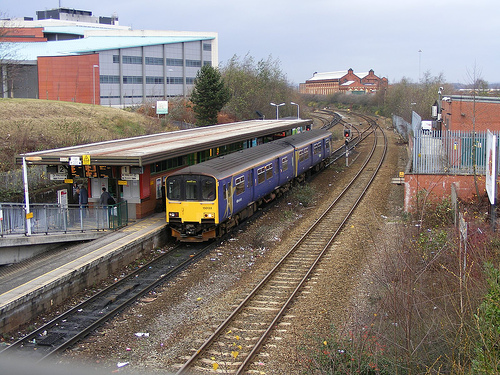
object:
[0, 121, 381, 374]
tracks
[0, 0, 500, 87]
sky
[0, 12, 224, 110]
building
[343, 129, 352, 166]
lights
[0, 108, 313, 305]
train station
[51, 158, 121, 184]
billboard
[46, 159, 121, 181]
information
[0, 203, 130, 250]
access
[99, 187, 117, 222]
person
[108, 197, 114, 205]
backpack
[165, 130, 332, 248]
train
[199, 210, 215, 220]
light